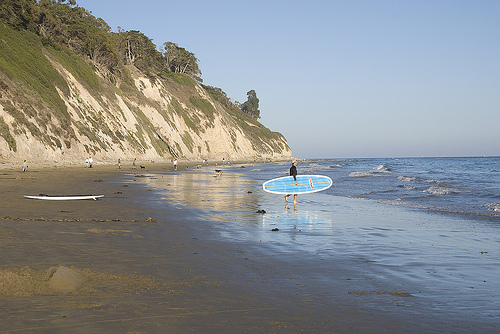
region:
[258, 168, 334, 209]
man is carrying a surfboard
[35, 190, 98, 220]
surfboard laying on sand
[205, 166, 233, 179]
people in the water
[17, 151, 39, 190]
person walking on the beach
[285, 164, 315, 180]
surfer is wearing a wet suit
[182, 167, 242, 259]
water on the sand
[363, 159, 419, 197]
waves in the ocean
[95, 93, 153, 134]
grass of the cliff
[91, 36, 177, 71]
trees on the cliff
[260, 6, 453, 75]
sky is clear blue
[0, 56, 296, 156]
green grass and rocks on a steep slope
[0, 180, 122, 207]
white surfboard laying on the beach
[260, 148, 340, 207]
person with black wetsuit carrying a blue surfboard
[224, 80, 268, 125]
green tree on a steep slope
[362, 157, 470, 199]
white waves in the blue ocean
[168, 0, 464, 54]
blue sky over the ocean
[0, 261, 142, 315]
pile of loose sand on the beach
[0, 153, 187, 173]
people walking on a sandy beach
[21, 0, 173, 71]
trees at the top of a steep slope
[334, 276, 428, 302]
bit of seaweed on a wet beach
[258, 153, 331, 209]
A man holding a blue and white surfboard.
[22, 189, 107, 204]
A surfboard lying on the sand.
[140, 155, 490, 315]
Wet sand along the shore.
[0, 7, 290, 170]
A hillside on the beach.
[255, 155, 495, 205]
Rolling waves on the water.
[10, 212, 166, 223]
Footprints in the sand.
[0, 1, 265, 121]
Trees along the top of the hill.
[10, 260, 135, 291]
A small pile of brown sand.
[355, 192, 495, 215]
Water rolling onto the shore.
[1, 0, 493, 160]
Blue skys above the water.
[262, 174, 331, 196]
light blue and white surfboard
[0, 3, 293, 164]
big mountain with green grass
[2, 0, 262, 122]
small trees on big mountain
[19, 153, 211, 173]
people walking on seashore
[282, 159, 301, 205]
man standing on seashore with sirfboard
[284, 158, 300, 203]
surfer with black wetsuit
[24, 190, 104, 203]
white surfboard on the seashore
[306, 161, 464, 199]
little white waves on sea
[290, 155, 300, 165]
gray cap of surfer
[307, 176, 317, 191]
little orange symbol on surfboard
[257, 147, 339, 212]
person carrying a surfboard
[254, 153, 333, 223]
blond carrying a surfboard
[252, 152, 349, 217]
person in a wetsuit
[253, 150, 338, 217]
person carrying a blue surfboard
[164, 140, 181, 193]
person on the beach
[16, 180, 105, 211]
surfboard on the beach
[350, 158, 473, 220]
waves coming toward shore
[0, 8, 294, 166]
hill above the beach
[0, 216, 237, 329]
nice sandy beach area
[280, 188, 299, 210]
bare legs of the surfer